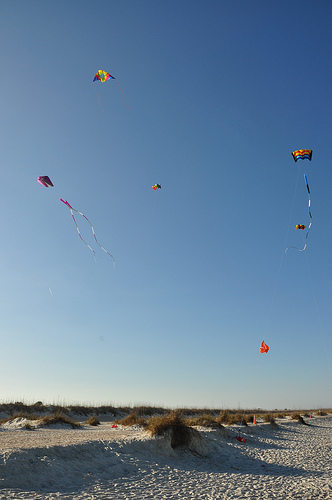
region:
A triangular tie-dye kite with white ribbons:
[92, 68, 128, 110]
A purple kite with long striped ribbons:
[36, 174, 117, 268]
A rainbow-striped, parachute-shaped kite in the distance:
[151, 182, 161, 191]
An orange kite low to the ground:
[260, 339, 268, 352]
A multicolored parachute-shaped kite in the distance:
[293, 223, 305, 231]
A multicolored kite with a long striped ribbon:
[285, 147, 313, 251]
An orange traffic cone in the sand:
[252, 414, 257, 423]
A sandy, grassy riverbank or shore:
[0, 400, 331, 498]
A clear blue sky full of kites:
[0, 0, 331, 410]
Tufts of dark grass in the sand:
[0, 399, 330, 446]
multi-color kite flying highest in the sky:
[91, 67, 132, 113]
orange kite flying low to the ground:
[257, 340, 270, 354]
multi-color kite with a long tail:
[290, 147, 315, 256]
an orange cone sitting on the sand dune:
[252, 413, 259, 423]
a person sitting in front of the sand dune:
[234, 427, 246, 442]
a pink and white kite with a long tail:
[38, 174, 118, 271]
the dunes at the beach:
[1, 399, 331, 430]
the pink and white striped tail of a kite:
[58, 195, 117, 268]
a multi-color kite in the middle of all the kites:
[151, 181, 162, 191]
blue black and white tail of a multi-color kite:
[287, 172, 313, 268]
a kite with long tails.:
[29, 166, 120, 263]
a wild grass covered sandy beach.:
[1, 398, 330, 498]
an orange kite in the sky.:
[239, 331, 281, 363]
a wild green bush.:
[144, 401, 203, 457]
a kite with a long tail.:
[279, 130, 330, 274]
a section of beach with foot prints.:
[253, 427, 311, 484]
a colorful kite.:
[30, 167, 124, 258]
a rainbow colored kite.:
[71, 54, 202, 199]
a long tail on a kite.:
[292, 168, 318, 269]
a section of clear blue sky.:
[104, 260, 223, 339]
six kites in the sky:
[34, 63, 312, 355]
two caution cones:
[247, 406, 330, 421]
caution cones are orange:
[244, 414, 322, 432]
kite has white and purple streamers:
[54, 188, 116, 283]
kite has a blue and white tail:
[284, 177, 317, 269]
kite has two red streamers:
[84, 65, 173, 127]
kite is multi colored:
[132, 174, 185, 201]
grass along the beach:
[122, 401, 328, 443]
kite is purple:
[25, 162, 64, 191]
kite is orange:
[243, 333, 287, 367]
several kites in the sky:
[26, 62, 318, 405]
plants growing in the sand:
[151, 410, 196, 462]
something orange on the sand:
[252, 419, 259, 426]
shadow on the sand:
[8, 446, 116, 492]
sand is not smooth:
[162, 479, 297, 498]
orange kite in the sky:
[257, 340, 282, 354]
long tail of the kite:
[301, 164, 319, 247]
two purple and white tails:
[57, 192, 118, 265]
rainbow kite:
[280, 137, 318, 172]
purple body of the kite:
[35, 168, 61, 191]